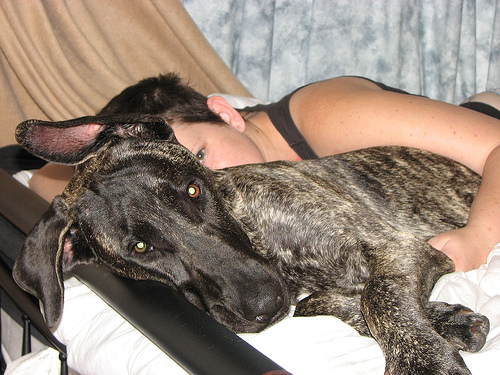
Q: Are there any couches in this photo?
A: No, there are no couches.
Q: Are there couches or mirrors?
A: No, there are no couches or mirrors.